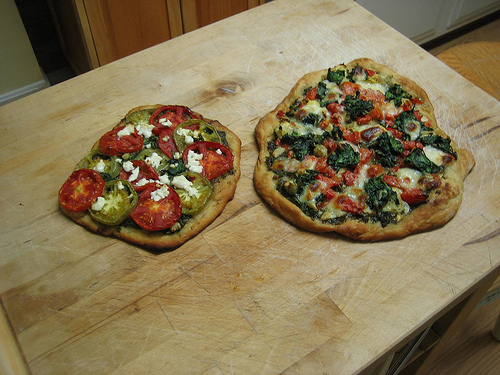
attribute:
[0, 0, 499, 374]
table — wooden, scratched, brown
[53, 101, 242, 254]
pizza — cooked, small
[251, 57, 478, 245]
pizza — cooked, medium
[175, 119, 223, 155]
tomato — green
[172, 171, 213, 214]
tomato — green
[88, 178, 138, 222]
tomato — green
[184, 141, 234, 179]
tomato — red, sliced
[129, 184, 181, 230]
tomato — red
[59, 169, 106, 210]
tomato — red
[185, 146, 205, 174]
feta cheese — white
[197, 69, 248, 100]
spot — dark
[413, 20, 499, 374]
floor — wooden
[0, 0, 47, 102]
wall — yellow, green